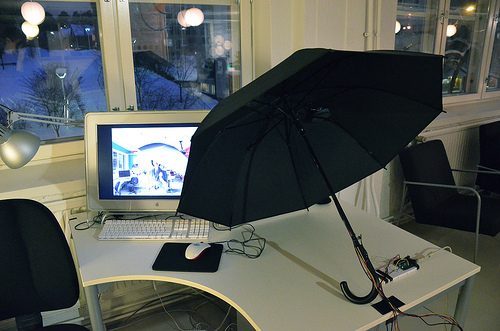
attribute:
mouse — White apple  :
[184, 240, 210, 259]